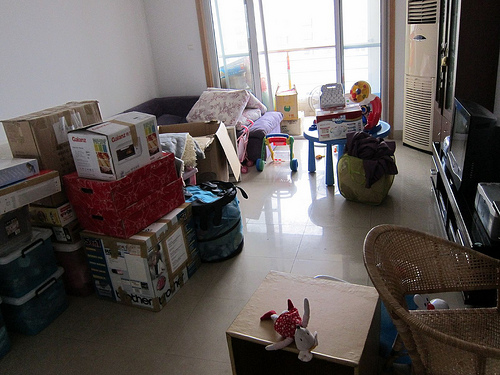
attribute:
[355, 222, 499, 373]
chair — wicker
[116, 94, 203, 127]
sofa — blue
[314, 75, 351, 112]
lunch bag — insulated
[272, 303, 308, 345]
shirt — red, white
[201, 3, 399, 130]
window — large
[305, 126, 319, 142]
blue table — round-topped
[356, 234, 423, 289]
chair — brown, straw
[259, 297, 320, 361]
doll — child's, mouse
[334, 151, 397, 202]
hamper — green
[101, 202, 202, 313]
box — large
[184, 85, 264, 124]
cushion — white, brown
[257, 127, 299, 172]
toy — child's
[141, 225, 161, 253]
tape — strips, brown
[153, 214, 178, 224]
tape — strips, brown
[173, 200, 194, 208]
tape — strips, brown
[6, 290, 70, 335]
bin — large, stacked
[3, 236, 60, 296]
bin — large, stacked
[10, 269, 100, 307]
lid — white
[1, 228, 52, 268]
lid — white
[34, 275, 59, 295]
handle — black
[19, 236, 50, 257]
handle — black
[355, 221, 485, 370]
chair — straw, brown